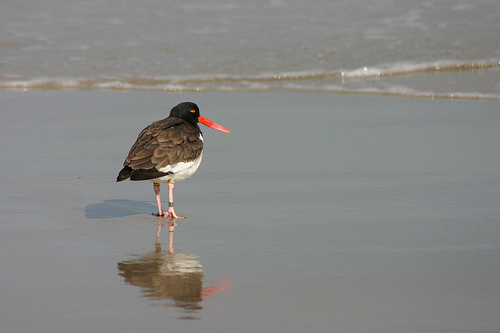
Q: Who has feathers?
A: A bird.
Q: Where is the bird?
A: On a beach.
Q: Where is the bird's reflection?
A: On the sand.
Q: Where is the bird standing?
A: Sandy beach.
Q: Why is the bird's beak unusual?
A: Long and red.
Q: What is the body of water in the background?
A: Ocean.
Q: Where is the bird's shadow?
A: Shallow beach water.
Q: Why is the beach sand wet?
A: Tide went out.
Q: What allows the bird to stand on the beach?
A: Legs.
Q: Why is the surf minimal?
A: Calm ocean.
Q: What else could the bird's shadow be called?
A: Reflection.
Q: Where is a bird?
A: On the beach.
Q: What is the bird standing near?
A: Ocean water.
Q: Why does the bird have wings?
A: To fly.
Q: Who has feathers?
A: The bird.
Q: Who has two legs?
A: A bird.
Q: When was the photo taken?
A: During the daytime.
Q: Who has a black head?
A: The bird.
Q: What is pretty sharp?
A: Bird's beak.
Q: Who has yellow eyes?
A: A bird.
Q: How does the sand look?
A: It is brown and wet.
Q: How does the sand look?
A: It is brown.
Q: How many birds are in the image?
A: 1.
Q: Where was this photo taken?
A: On a beach.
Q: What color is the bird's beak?
A: Orange.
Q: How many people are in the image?
A: 0.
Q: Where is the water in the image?
A: Be hide the bird.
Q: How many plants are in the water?
A: 0.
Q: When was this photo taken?
A: Daytime.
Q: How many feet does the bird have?
A: 2.